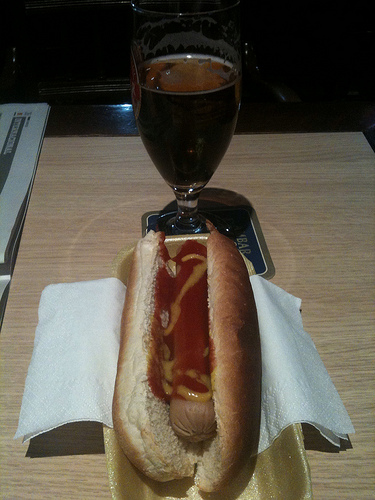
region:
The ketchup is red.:
[194, 300, 205, 352]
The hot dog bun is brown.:
[242, 321, 254, 386]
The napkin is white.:
[64, 310, 94, 376]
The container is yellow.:
[269, 456, 300, 482]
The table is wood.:
[76, 155, 110, 212]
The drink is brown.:
[158, 100, 215, 147]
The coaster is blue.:
[235, 219, 250, 235]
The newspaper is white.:
[29, 127, 40, 144]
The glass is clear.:
[172, 41, 215, 62]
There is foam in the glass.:
[154, 36, 215, 48]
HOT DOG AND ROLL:
[130, 225, 256, 481]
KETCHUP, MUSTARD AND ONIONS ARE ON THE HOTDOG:
[156, 252, 225, 448]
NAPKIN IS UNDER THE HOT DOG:
[18, 276, 350, 434]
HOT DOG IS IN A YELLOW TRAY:
[91, 216, 309, 494]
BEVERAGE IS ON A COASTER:
[138, 201, 286, 291]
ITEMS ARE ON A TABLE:
[23, 128, 363, 395]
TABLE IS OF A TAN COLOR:
[41, 141, 367, 493]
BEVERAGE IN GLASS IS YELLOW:
[111, 3, 258, 214]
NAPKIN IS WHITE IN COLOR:
[19, 270, 357, 449]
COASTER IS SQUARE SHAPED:
[141, 210, 278, 274]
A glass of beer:
[127, 23, 236, 234]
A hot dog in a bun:
[120, 231, 262, 496]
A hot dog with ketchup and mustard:
[123, 233, 260, 485]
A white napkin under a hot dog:
[16, 239, 358, 488]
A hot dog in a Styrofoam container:
[104, 232, 320, 498]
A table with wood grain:
[259, 130, 374, 264]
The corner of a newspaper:
[2, 99, 53, 273]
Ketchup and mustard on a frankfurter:
[166, 242, 212, 438]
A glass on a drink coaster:
[127, 2, 279, 280]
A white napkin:
[14, 277, 117, 437]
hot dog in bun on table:
[109, 217, 242, 498]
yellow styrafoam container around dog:
[79, 451, 316, 493]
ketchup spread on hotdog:
[163, 256, 215, 404]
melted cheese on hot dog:
[167, 246, 207, 408]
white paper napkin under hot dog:
[27, 281, 360, 442]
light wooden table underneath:
[36, 141, 369, 459]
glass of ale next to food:
[147, 55, 237, 172]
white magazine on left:
[0, 105, 64, 264]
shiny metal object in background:
[98, 99, 133, 130]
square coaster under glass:
[129, 194, 299, 286]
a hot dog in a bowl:
[91, 218, 314, 498]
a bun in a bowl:
[100, 219, 313, 497]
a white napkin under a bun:
[19, 267, 358, 458]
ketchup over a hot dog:
[117, 215, 264, 491]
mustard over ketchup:
[116, 221, 261, 492]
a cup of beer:
[120, 1, 246, 232]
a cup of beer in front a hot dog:
[107, 7, 280, 498]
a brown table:
[17, 5, 373, 496]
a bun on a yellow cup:
[93, 216, 316, 498]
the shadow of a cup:
[122, 138, 270, 244]